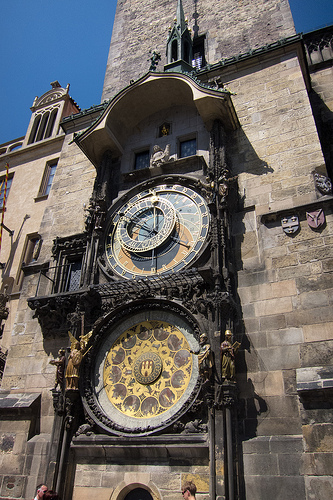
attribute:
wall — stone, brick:
[1, 53, 331, 500]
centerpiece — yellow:
[133, 351, 162, 386]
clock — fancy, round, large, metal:
[94, 174, 214, 280]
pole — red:
[0, 161, 12, 270]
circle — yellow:
[77, 298, 209, 440]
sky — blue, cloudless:
[0, 0, 332, 148]